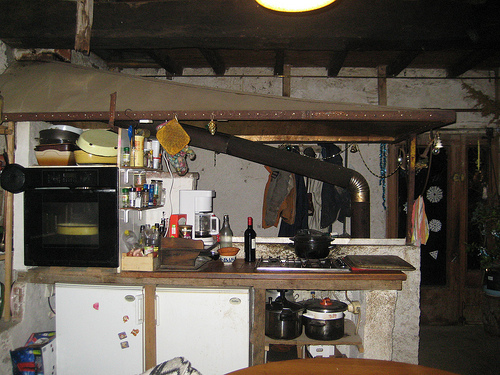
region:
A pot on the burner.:
[266, 229, 335, 262]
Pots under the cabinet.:
[270, 290, 344, 331]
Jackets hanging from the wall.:
[257, 155, 336, 218]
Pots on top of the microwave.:
[33, 123, 120, 174]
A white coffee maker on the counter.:
[183, 177, 228, 247]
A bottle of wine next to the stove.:
[236, 209, 258, 266]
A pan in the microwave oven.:
[41, 200, 107, 241]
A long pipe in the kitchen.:
[211, 136, 393, 201]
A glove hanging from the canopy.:
[164, 143, 209, 177]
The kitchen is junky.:
[117, 165, 202, 270]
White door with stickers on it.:
[54, 283, 149, 373]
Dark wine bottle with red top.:
[244, 207, 257, 266]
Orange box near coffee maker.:
[168, 211, 188, 238]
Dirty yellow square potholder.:
[153, 115, 198, 156]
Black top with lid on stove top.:
[287, 220, 334, 262]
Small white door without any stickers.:
[155, 287, 251, 373]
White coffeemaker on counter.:
[180, 186, 220, 241]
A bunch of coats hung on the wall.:
[261, 147, 351, 232]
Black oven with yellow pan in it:
[23, 167, 120, 267]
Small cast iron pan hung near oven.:
[0, 146, 27, 198]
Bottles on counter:
[220, 202, 267, 274]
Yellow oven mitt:
[154, 119, 188, 154]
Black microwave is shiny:
[22, 176, 113, 262]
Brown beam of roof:
[66, 2, 106, 47]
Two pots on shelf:
[272, 292, 351, 343]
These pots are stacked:
[310, 311, 342, 334]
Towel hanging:
[417, 188, 429, 242]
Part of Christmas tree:
[457, 80, 497, 122]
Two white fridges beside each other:
[51, 287, 246, 369]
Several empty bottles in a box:
[122, 228, 166, 251]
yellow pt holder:
[149, 111, 192, 161]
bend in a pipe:
[316, 157, 385, 212]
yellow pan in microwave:
[52, 206, 118, 250]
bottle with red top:
[241, 213, 261, 264]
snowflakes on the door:
[425, 183, 450, 233]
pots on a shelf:
[267, 292, 349, 342]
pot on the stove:
[286, 225, 331, 263]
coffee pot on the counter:
[173, 183, 225, 248]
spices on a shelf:
[121, 171, 163, 211]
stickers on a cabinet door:
[83, 298, 143, 355]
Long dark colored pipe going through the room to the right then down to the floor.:
[118, 111, 372, 238]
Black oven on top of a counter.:
[25, 163, 121, 268]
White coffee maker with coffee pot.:
[175, 185, 221, 247]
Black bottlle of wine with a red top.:
[241, 215, 256, 261]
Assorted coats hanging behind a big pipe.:
[263, 136, 353, 235]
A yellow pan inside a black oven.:
[53, 220, 99, 237]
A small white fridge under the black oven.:
[50, 279, 146, 374]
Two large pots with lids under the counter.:
[265, 297, 347, 341]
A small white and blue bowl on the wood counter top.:
[217, 252, 237, 267]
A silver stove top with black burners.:
[254, 252, 347, 275]